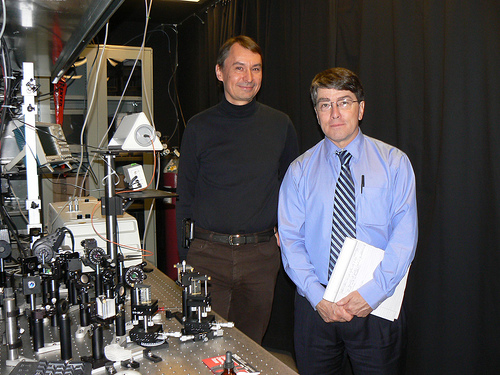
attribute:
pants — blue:
[294, 283, 404, 373]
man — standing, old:
[277, 64, 419, 374]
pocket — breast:
[355, 184, 392, 229]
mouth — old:
[314, 114, 355, 138]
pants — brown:
[182, 215, 275, 320]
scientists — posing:
[182, 40, 429, 326]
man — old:
[296, 65, 398, 305]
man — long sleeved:
[178, 36, 288, 340]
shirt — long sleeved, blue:
[271, 121, 419, 321]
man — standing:
[173, 33, 303, 345]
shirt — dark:
[173, 86, 291, 291]